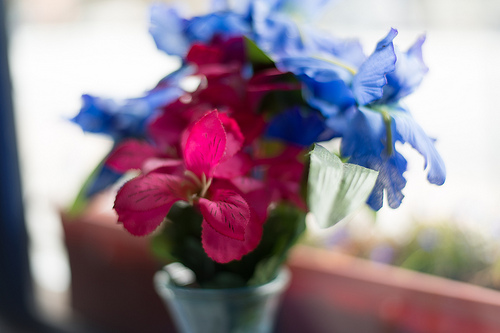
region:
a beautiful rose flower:
[111, 103, 342, 330]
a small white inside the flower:
[184, 168, 234, 207]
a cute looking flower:
[131, 100, 253, 238]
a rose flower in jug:
[119, 78, 298, 287]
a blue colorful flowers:
[163, 12, 498, 202]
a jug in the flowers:
[142, 265, 287, 325]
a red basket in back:
[50, 190, 493, 327]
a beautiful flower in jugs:
[52, 7, 438, 310]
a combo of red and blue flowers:
[134, 20, 481, 195]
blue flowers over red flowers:
[177, 7, 457, 240]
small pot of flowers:
[71, 7, 423, 329]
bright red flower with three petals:
[118, 102, 278, 271]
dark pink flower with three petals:
[115, 99, 289, 256]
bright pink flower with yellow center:
[113, 95, 295, 272]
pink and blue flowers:
[86, 2, 449, 268]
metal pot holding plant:
[148, 253, 303, 332]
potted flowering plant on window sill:
[84, 22, 399, 324]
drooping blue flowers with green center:
[262, 6, 454, 210]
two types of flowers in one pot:
[76, 2, 429, 314]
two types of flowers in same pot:
[76, 0, 461, 326]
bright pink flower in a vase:
[112, 107, 257, 247]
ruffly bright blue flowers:
[56, 4, 453, 216]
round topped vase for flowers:
[142, 250, 301, 331]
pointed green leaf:
[303, 138, 380, 234]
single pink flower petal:
[182, 105, 227, 176]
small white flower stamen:
[175, 157, 213, 202]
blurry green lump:
[325, 210, 487, 286]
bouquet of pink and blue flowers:
[47, 3, 462, 285]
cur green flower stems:
[130, 200, 312, 284]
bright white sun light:
[0, 0, 499, 332]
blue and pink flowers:
[51, 2, 467, 272]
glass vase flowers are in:
[146, 249, 288, 331]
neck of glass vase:
[167, 301, 275, 332]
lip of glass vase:
[146, 260, 292, 300]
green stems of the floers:
[155, 227, 287, 279]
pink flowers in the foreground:
[87, 50, 315, 255]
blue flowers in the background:
[53, 0, 433, 217]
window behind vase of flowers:
[13, 13, 488, 307]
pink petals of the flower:
[115, 119, 270, 245]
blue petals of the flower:
[292, 25, 443, 203]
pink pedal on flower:
[184, 116, 231, 164]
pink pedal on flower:
[195, 189, 244, 223]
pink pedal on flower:
[127, 176, 185, 219]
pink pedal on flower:
[113, 141, 143, 168]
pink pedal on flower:
[150, 105, 183, 145]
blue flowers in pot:
[156, 5, 466, 187]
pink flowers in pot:
[130, 70, 297, 232]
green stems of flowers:
[147, 206, 295, 281]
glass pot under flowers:
[152, 266, 308, 331]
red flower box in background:
[70, 209, 490, 326]